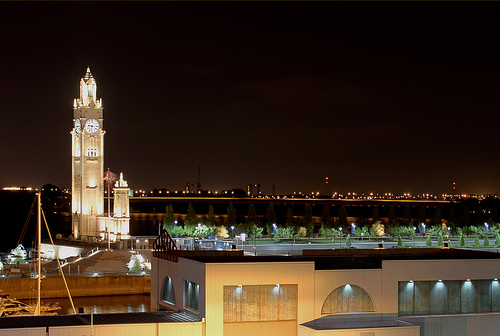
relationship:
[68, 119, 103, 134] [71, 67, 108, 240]
clocks on clock tower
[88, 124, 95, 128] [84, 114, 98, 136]
black hands of clock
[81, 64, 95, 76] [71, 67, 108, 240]
spire on clock tower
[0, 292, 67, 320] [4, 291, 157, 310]
boat in water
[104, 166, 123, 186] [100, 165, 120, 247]
flag on pole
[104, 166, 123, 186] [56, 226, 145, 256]
flag on building